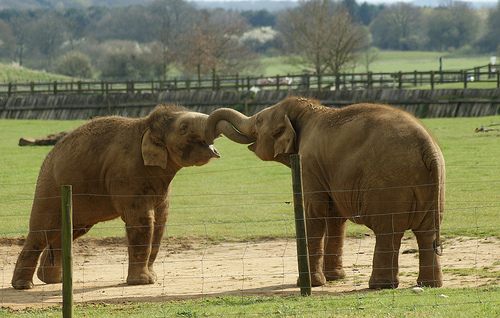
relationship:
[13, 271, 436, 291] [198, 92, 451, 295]
toe nails on elephant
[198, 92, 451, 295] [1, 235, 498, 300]
elephant in patch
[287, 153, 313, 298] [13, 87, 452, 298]
fence post by elephants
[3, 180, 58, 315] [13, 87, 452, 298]
wire by elephants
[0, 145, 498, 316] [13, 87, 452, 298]
fencing by elephants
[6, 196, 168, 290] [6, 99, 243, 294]
legs on elephant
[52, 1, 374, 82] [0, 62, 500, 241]
trees in pen